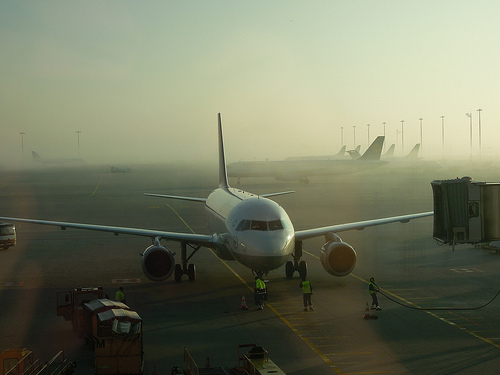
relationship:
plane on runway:
[11, 130, 391, 268] [31, 251, 144, 295]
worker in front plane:
[289, 275, 326, 308] [11, 130, 391, 268]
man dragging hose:
[370, 270, 389, 323] [387, 280, 492, 326]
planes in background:
[247, 148, 418, 188] [214, 46, 402, 119]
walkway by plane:
[425, 170, 496, 256] [11, 130, 391, 268]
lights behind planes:
[304, 89, 496, 137] [247, 148, 418, 188]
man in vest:
[370, 270, 389, 323] [299, 282, 318, 290]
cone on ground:
[368, 300, 377, 337] [404, 230, 456, 310]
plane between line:
[11, 130, 391, 268] [267, 321, 336, 365]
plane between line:
[11, 130, 391, 268] [423, 287, 483, 346]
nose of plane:
[230, 238, 305, 269] [11, 130, 391, 268]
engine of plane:
[308, 220, 364, 270] [11, 130, 391, 268]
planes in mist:
[247, 148, 418, 188] [369, 55, 499, 116]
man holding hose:
[370, 270, 389, 323] [387, 280, 492, 326]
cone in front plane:
[368, 300, 377, 337] [11, 130, 391, 268]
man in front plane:
[370, 270, 389, 323] [11, 130, 391, 268]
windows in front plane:
[224, 197, 297, 241] [11, 130, 391, 268]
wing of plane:
[13, 199, 218, 262] [11, 130, 391, 268]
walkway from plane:
[425, 170, 496, 256] [11, 130, 391, 268]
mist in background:
[369, 55, 499, 116] [214, 46, 402, 119]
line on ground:
[267, 321, 336, 365] [404, 230, 456, 310]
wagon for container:
[57, 280, 172, 359] [56, 267, 106, 306]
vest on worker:
[299, 282, 318, 290] [289, 275, 326, 308]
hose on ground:
[387, 280, 492, 326] [404, 230, 456, 310]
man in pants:
[370, 270, 389, 323] [293, 293, 326, 307]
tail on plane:
[186, 92, 249, 192] [11, 130, 391, 268]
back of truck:
[172, 353, 207, 367] [174, 341, 291, 373]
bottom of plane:
[239, 249, 301, 274] [11, 130, 391, 268]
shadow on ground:
[128, 276, 268, 345] [404, 230, 456, 310]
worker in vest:
[289, 275, 326, 308] [299, 282, 318, 290]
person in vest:
[250, 264, 285, 309] [299, 282, 318, 290]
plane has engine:
[11, 130, 391, 268] [308, 220, 364, 270]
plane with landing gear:
[11, 130, 391, 268] [172, 260, 203, 291]